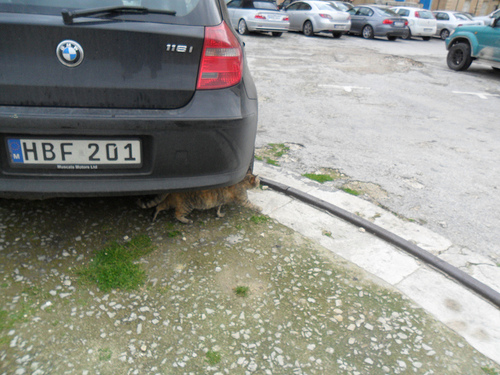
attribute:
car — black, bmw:
[1, 0, 259, 199]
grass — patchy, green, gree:
[84, 225, 189, 306]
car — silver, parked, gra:
[286, 1, 355, 45]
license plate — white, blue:
[1, 125, 155, 174]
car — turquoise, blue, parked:
[447, 16, 499, 85]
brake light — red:
[195, 15, 246, 100]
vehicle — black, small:
[220, 2, 295, 46]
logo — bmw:
[54, 37, 88, 66]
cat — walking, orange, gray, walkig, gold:
[133, 171, 260, 223]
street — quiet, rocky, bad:
[268, 44, 496, 266]